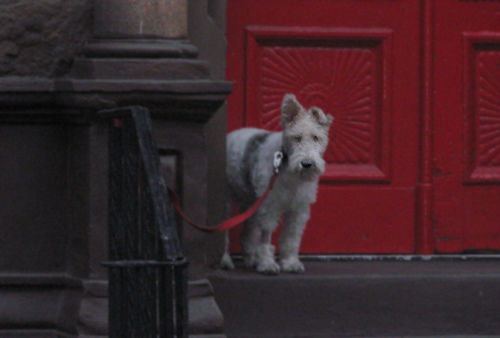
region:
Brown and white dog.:
[216, 93, 337, 271]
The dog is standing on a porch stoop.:
[218, 96, 498, 336]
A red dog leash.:
[140, 160, 285, 235]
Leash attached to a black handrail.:
[105, 115, 191, 335]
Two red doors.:
[227, 2, 497, 257]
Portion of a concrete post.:
[82, 0, 207, 75]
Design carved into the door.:
[255, 39, 380, 164]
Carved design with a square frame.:
[245, 23, 393, 183]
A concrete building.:
[0, 0, 221, 335]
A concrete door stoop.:
[207, 254, 499, 336]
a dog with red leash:
[111, 69, 352, 281]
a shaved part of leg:
[248, 211, 285, 256]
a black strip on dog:
[236, 126, 280, 199]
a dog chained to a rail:
[83, 100, 320, 337]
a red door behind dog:
[231, 11, 498, 272]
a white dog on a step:
[224, 76, 354, 291]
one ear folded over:
[306, 94, 343, 129]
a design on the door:
[241, 23, 425, 213]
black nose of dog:
[302, 151, 316, 172]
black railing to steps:
[92, 100, 225, 335]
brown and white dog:
[228, 95, 333, 273]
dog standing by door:
[229, 95, 330, 274]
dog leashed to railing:
[226, 93, 331, 275]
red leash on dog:
[137, 155, 282, 236]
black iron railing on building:
[101, 107, 188, 337]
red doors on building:
[227, 1, 498, 255]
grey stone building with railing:
[1, 2, 227, 334]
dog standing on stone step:
[230, 93, 334, 276]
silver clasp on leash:
[271, 150, 283, 171]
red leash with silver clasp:
[139, 151, 280, 238]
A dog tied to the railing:
[200, 78, 357, 277]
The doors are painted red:
[362, 11, 464, 253]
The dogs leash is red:
[184, 132, 285, 274]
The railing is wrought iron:
[86, 91, 208, 329]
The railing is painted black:
[98, 103, 196, 320]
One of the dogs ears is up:
[272, 89, 306, 128]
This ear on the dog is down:
[307, 105, 341, 130]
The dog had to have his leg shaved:
[258, 209, 279, 263]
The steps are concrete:
[340, 249, 418, 317]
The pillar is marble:
[104, 1, 214, 81]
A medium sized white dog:
[208, 88, 334, 277]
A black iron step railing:
[92, 97, 197, 337]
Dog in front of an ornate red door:
[223, 3, 498, 261]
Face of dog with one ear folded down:
[274, 88, 334, 185]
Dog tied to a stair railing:
[89, 90, 339, 285]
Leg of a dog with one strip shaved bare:
[253, 208, 278, 271]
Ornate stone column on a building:
[62, 0, 235, 337]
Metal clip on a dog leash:
[268, 150, 285, 176]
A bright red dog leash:
[167, 151, 283, 237]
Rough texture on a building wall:
[2, 2, 89, 75]